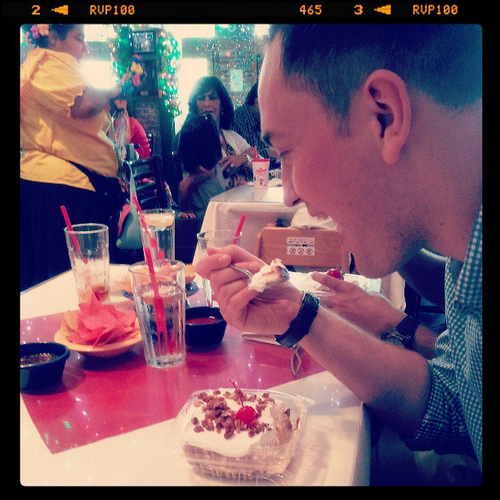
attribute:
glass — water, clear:
[127, 255, 189, 372]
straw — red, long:
[141, 245, 178, 357]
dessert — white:
[177, 387, 296, 483]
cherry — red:
[237, 400, 259, 428]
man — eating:
[190, 21, 485, 471]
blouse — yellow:
[15, 47, 119, 196]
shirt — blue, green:
[412, 203, 487, 477]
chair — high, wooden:
[126, 150, 172, 207]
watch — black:
[272, 293, 320, 348]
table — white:
[19, 265, 384, 485]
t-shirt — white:
[214, 126, 271, 191]